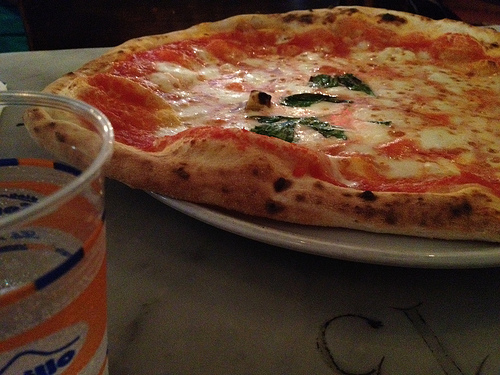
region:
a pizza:
[35, 86, 442, 326]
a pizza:
[107, 17, 499, 289]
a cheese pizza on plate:
[24, 19, 495, 323]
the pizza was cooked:
[160, 76, 358, 222]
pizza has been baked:
[146, 62, 403, 244]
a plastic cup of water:
[11, 64, 191, 348]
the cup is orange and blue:
[28, 71, 198, 291]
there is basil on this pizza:
[204, 76, 416, 196]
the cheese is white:
[197, 31, 404, 191]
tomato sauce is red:
[201, 34, 479, 244]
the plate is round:
[63, 23, 381, 281]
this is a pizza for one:
[27, 14, 491, 309]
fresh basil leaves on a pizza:
[253, 63, 373, 141]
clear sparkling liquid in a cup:
[7, 161, 50, 199]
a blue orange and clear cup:
[6, 147, 118, 362]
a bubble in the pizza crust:
[171, 126, 312, 206]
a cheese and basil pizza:
[79, 41, 484, 201]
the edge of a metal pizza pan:
[243, 217, 493, 269]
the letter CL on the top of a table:
[299, 301, 483, 370]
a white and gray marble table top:
[103, 220, 227, 372]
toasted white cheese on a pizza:
[417, 127, 457, 147]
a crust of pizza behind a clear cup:
[3, 68, 134, 185]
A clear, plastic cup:
[1, 85, 119, 373]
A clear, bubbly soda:
[2, 170, 118, 373]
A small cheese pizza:
[45, 2, 497, 295]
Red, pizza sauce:
[95, 51, 187, 157]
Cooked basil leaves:
[252, 59, 382, 157]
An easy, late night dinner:
[2, 5, 493, 362]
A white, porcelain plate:
[120, 142, 494, 305]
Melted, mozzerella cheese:
[144, 36, 498, 189]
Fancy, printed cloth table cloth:
[2, 38, 498, 371]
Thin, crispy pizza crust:
[39, 72, 496, 236]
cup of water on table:
[1, 111, 118, 368]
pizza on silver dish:
[108, 3, 491, 243]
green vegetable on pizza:
[274, 114, 348, 138]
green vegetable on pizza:
[327, 70, 362, 92]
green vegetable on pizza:
[277, 92, 343, 109]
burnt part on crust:
[260, 199, 287, 220]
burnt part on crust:
[268, 180, 288, 195]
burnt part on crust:
[356, 187, 378, 204]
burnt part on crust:
[378, 210, 400, 224]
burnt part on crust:
[446, 199, 478, 221]